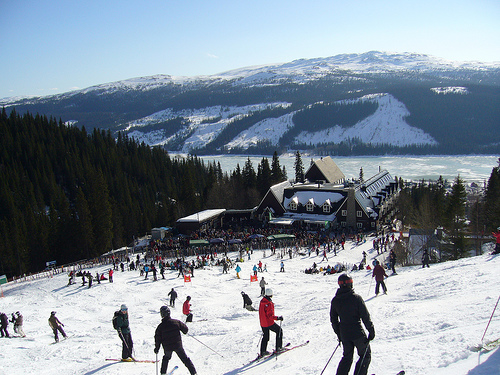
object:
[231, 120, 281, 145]
snow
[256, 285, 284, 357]
person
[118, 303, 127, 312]
hat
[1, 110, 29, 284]
pines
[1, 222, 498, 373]
slope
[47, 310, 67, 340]
skier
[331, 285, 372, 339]
jacket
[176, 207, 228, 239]
building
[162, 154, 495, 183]
lake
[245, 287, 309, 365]
ski outfit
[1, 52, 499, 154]
mountain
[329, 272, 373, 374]
people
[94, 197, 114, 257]
tree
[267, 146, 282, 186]
tree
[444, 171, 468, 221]
tree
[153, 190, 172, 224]
tree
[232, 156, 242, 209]
tree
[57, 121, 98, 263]
trees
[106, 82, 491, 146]
slopes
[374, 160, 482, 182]
water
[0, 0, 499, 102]
sky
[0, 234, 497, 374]
snow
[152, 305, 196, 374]
person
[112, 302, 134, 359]
person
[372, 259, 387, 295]
person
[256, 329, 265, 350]
ski poles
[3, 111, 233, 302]
hillside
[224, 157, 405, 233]
building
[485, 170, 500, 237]
trees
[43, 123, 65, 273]
trees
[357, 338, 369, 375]
poles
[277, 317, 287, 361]
poles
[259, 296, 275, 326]
coat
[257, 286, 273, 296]
hat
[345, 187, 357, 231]
chimney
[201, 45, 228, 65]
clouds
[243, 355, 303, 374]
snow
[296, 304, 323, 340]
snow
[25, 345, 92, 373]
snow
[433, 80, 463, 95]
clearing